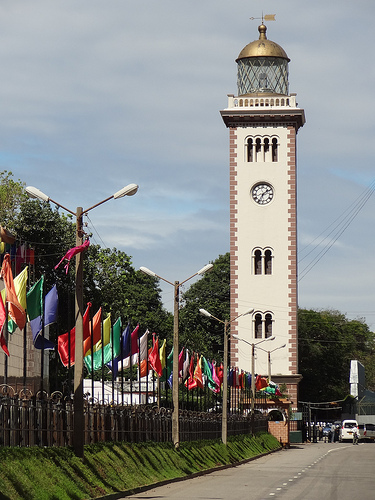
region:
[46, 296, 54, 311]
the flag is blue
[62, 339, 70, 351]
the flag is red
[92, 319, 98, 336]
the flag is orange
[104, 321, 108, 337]
the flag is yellow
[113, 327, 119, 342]
the flag is green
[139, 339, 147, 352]
the flag is white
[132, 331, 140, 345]
the flag is pink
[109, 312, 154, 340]
flag's are hooked to the fence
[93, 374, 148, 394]
the fence is black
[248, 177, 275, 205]
clock is on the building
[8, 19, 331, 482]
this is an urban area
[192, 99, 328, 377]
this is a building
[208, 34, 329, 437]
the building is tall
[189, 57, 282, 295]
this is a tower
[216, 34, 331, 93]
the tower top is domed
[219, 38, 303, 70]
the dome is golden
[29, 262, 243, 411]
these are rows of flags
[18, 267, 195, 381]
the flags are colorful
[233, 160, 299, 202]
this is a clock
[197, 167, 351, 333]
the tower is white and brown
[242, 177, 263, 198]
a clock on a building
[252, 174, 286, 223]
a large clock on a building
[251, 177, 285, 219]
an outside clock on a building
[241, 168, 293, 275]
a large outside clock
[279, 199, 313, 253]
a clock that is outside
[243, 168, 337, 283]
a building with a clock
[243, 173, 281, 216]
a building with a large clock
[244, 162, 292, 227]
a building with an outside clock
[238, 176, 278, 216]
a building with a large outside clock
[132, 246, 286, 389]
lights on a pole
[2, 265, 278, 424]
long row of different colored flags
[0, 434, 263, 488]
shadows of row of flags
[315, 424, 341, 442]
group od people standing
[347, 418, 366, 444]
man walking behind a vehicle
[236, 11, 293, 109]
weather vein a top of building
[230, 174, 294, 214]
round clock design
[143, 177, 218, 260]
clouds have a haze to them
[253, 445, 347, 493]
white painted dash lines divides the road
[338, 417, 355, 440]
back end of a white vehicle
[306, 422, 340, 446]
group of people standing inline to get in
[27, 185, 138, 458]
a double sided street light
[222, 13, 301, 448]
a brick and plastered white lighthouse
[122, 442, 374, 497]
a paved asphalt street with a white dotted line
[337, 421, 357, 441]
the back of a white pasenger van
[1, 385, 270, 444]
a black wrought iron fence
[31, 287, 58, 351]
a blue flag waving in the wind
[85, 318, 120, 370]
a green flag flying in the wind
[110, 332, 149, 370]
a white flag flying in the wind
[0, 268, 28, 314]
a yellow flag flying in the wind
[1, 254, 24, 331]
an orange flag slightly moving in the wind